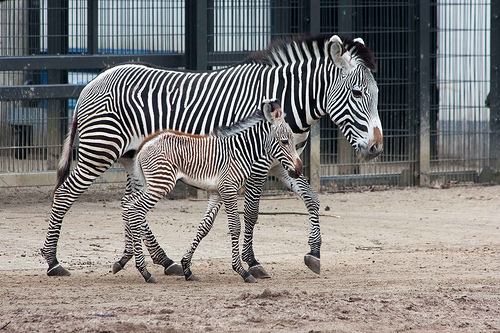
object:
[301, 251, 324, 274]
hoof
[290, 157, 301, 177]
nose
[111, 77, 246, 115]
stripped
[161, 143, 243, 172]
stripped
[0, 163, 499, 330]
floor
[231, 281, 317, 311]
soil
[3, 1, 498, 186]
cage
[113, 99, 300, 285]
baby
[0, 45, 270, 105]
bars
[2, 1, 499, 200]
fence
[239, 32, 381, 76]
mane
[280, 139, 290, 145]
eye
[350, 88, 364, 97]
eye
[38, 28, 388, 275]
adult zebra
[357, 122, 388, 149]
nose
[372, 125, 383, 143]
marking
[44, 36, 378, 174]
stripes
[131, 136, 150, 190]
tail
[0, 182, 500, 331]
dirt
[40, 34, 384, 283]
couple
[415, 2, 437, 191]
post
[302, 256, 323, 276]
hoof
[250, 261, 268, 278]
hoof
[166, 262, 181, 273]
hoof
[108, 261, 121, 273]
hoof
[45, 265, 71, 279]
hoofs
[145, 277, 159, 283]
hoofs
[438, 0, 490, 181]
fencing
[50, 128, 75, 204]
hair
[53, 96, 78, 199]
tail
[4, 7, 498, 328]
pen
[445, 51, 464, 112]
wires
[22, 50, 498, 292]
enclosure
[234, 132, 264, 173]
stripes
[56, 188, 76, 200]
fur